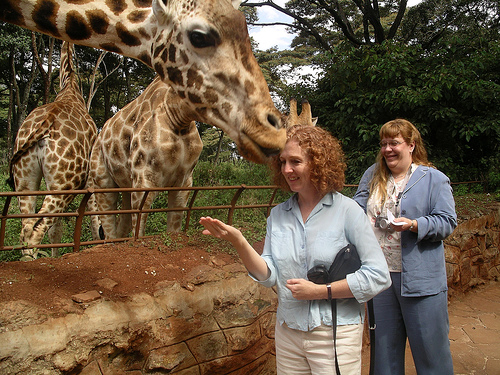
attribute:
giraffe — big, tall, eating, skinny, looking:
[23, 2, 280, 229]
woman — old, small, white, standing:
[212, 118, 387, 372]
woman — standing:
[344, 113, 486, 343]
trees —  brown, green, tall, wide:
[4, 3, 497, 193]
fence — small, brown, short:
[4, 174, 360, 251]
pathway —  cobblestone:
[450, 273, 496, 373]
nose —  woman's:
[284, 163, 291, 173]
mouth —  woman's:
[288, 175, 304, 183]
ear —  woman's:
[408, 136, 414, 152]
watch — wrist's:
[326, 280, 332, 301]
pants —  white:
[273, 325, 365, 373]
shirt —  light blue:
[248, 190, 391, 329]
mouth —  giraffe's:
[232, 128, 281, 166]